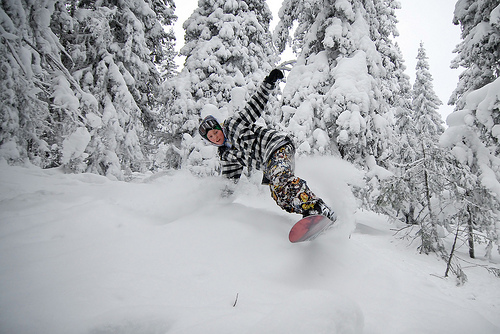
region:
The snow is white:
[207, 209, 234, 246]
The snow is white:
[184, 258, 208, 290]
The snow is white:
[191, 300, 214, 316]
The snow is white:
[248, 320, 268, 332]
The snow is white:
[258, 268, 291, 295]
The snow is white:
[263, 298, 284, 313]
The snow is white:
[258, 308, 278, 315]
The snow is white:
[231, 274, 247, 288]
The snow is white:
[232, 287, 257, 312]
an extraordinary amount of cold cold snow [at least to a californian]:
[1, 3, 498, 332]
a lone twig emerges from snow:
[223, 284, 245, 310]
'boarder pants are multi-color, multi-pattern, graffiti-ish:
[259, 138, 330, 217]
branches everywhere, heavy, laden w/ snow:
[0, 24, 145, 182]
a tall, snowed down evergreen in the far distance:
[408, 37, 448, 156]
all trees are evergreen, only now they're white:
[2, 1, 499, 289]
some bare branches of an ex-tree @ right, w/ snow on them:
[357, 127, 495, 285]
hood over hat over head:
[195, 110, 230, 145]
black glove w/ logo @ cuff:
[260, 62, 285, 88]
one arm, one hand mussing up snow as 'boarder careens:
[193, 170, 248, 207]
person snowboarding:
[186, 69, 356, 249]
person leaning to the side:
[182, 65, 362, 252]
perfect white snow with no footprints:
[4, 178, 499, 330]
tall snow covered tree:
[404, 36, 443, 158]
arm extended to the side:
[231, 64, 291, 117]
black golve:
[266, 67, 286, 85]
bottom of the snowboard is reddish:
[288, 213, 333, 243]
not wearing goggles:
[206, 127, 223, 144]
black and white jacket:
[218, 78, 280, 213]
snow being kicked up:
[186, 171, 246, 216]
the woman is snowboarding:
[160, 49, 367, 258]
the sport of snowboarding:
[146, 48, 351, 239]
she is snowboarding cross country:
[113, 35, 392, 280]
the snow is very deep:
[36, 89, 178, 204]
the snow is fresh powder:
[102, 50, 448, 307]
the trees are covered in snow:
[18, 20, 243, 254]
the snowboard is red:
[243, 212, 470, 329]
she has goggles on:
[156, 53, 375, 247]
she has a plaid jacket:
[153, 52, 415, 277]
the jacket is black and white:
[141, 25, 396, 262]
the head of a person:
[196, 106, 231, 150]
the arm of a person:
[227, 82, 273, 124]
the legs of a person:
[256, 141, 318, 214]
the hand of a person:
[263, 60, 288, 85]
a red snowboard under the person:
[286, 199, 348, 246]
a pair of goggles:
[197, 112, 224, 139]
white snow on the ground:
[2, 158, 499, 332]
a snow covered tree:
[411, 37, 445, 152]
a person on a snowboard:
[179, 62, 357, 252]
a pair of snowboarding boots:
[299, 193, 339, 226]